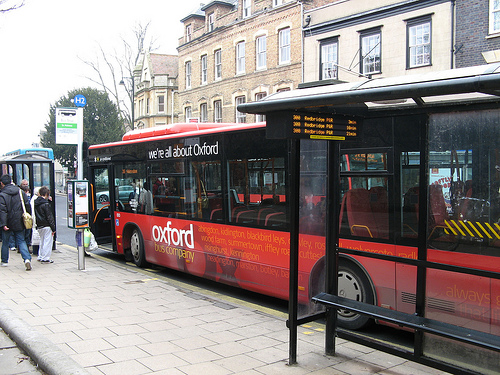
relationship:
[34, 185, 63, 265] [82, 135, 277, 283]
person standing near bus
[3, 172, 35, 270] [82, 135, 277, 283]
person standing near bus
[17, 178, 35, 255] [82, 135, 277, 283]
person standing near bus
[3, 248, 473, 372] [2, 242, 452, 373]
sidewalk covered with pavers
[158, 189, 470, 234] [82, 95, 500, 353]
seats on bus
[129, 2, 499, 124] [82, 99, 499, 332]
buildings on side of bus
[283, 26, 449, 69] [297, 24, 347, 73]
windows in black frames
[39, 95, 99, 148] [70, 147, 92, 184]
sign on metal pole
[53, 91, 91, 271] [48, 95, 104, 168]
pole with signs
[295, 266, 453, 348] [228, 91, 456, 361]
bench in shelter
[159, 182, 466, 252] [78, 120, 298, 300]
seats in bus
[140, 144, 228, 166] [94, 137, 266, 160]
message on black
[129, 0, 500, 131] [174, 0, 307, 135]
buildings next to building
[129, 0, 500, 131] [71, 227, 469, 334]
buildings on same side of street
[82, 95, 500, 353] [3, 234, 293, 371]
bus stopped at curb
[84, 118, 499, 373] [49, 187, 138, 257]
bus on road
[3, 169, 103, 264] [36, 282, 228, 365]
people on sidewalk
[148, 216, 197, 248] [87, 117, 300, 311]
white words on side of bus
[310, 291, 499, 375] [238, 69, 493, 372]
bench at bus stop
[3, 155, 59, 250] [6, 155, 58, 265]
black frame on bus stop